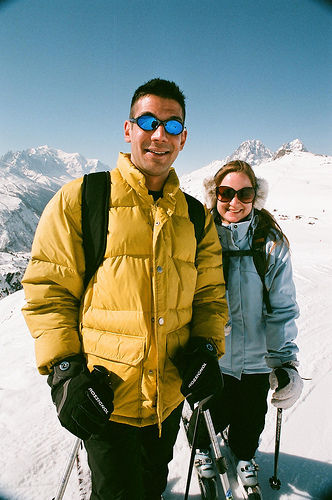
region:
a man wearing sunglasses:
[101, 57, 206, 201]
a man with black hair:
[87, 63, 199, 187]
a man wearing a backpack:
[43, 61, 229, 300]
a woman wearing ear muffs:
[196, 133, 270, 245]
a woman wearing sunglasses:
[194, 138, 274, 260]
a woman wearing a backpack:
[189, 137, 290, 302]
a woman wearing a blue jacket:
[194, 155, 314, 368]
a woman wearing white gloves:
[196, 152, 319, 411]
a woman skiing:
[179, 125, 275, 491]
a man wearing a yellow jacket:
[45, 68, 237, 295]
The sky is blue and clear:
[172, 63, 297, 147]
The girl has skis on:
[167, 413, 274, 493]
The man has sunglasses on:
[103, 102, 216, 166]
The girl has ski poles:
[257, 384, 296, 495]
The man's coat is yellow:
[42, 186, 196, 364]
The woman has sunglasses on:
[192, 164, 279, 229]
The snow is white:
[1, 383, 93, 497]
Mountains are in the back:
[205, 107, 330, 217]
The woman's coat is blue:
[225, 229, 323, 376]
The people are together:
[33, 87, 294, 413]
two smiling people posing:
[24, 77, 289, 388]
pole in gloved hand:
[261, 368, 297, 476]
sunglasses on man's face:
[134, 110, 191, 143]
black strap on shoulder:
[72, 163, 123, 247]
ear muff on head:
[250, 172, 277, 216]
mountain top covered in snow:
[12, 140, 84, 179]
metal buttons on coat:
[153, 259, 167, 329]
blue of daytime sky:
[250, 74, 310, 116]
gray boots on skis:
[185, 446, 267, 491]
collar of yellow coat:
[112, 148, 144, 185]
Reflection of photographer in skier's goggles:
[125, 110, 191, 142]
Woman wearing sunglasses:
[199, 162, 279, 265]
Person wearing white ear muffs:
[200, 173, 271, 223]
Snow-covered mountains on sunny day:
[4, 139, 109, 177]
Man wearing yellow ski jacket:
[60, 85, 218, 417]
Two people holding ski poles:
[43, 349, 303, 499]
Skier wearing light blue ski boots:
[175, 394, 271, 497]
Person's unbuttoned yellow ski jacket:
[133, 206, 167, 434]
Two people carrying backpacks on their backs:
[69, 178, 284, 302]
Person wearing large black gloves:
[45, 337, 229, 441]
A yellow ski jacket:
[17, 144, 238, 436]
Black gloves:
[35, 337, 233, 448]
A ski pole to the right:
[257, 347, 294, 498]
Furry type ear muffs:
[198, 154, 271, 220]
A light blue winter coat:
[182, 197, 301, 386]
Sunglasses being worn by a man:
[108, 100, 194, 149]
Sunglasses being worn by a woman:
[207, 172, 265, 216]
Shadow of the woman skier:
[210, 433, 327, 497]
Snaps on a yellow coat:
[149, 208, 165, 415]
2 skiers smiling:
[19, 67, 298, 491]